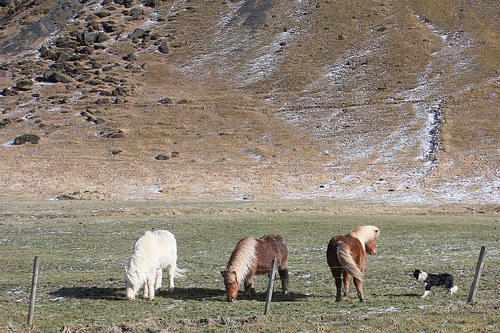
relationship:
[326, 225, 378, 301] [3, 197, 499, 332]
horse in field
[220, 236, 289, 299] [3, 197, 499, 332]
horse in field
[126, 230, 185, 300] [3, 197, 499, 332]
horse in field